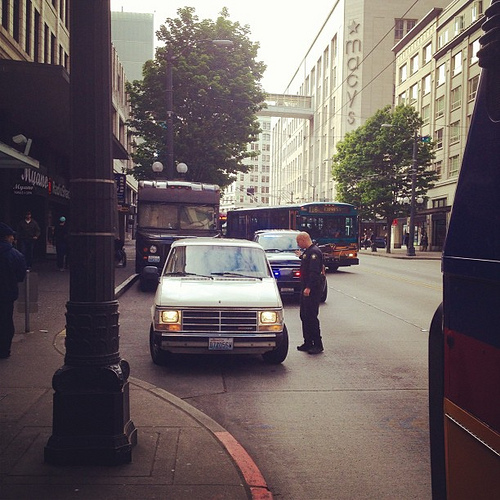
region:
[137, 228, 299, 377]
vehicle on a street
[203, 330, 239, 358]
front licence plate on a vehicle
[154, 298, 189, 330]
front headlight on a vehicle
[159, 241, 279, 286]
front windshield on a vehicle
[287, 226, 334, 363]
person with black pants standing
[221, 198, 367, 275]
bus on a street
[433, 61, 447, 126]
windows on a building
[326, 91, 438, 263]
green tree near a street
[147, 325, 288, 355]
front bumper on a vehicle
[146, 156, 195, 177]
street light on a pole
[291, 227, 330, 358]
police officer that pulled someone over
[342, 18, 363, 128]
macy's really large in stone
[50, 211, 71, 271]
guy with a light blue hat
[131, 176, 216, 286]
UPS truck blocked in by the police cruiser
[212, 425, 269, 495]
red paint on a curb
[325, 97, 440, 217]
smaller of the bushy trees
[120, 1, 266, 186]
larger of the bushy trees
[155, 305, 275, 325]
headlight of a van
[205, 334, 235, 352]
illinois license plate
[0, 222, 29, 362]
guy in all navy blue watching the action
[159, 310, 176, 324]
the headlight of the van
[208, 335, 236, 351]
the front tag of the van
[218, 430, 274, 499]
red painted curb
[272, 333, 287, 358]
the front tire of the van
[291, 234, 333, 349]
a police officer is standing in the street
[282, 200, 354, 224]
a city bus in the background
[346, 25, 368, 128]
macys building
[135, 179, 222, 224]
a truck parked behind the van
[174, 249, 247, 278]
the windshield of the van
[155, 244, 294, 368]
a van is stopped in the road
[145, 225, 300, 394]
A car is visible.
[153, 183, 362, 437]
A car is visible.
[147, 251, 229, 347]
A car is visible.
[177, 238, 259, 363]
A car is visible.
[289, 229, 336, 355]
a man standing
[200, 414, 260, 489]
a street curb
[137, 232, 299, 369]
a silver van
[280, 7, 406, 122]
a huge macy's store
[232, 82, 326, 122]
a city cat walk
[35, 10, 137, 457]
a black street lamp post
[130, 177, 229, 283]
a ups vehicle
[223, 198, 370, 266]
a city bus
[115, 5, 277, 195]
a big green tree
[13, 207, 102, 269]
people walking down the street